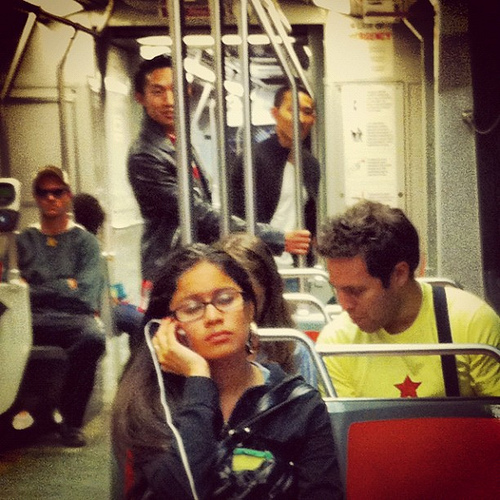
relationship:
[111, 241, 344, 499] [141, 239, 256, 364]
woman has a head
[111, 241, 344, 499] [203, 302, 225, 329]
woman has a nose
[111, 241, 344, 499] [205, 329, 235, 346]
woman has a mouth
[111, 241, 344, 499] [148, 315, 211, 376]
woman has a hand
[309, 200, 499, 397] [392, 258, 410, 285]
man has an ear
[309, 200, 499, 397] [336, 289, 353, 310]
man has a nose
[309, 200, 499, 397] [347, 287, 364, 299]
man has an eye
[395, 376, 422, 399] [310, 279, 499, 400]
star design on shirt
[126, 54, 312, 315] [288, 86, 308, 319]
man holding pole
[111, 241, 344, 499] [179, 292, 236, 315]
woman with closed eyes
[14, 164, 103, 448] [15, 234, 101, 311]
man crossed arms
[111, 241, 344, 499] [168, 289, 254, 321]
woman wearing glasses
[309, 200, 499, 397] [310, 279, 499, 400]
man in a shirt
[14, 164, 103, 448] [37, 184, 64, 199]
man wearing sunglasses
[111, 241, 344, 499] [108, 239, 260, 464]
woman has long hair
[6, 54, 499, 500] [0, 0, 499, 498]
people in a train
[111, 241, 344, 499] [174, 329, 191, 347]
woman holding device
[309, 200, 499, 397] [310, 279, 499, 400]
man in a yellow shirt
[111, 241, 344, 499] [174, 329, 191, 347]
woman on a cell phone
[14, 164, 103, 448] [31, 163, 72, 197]
man in a hat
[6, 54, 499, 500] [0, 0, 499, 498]
people on a train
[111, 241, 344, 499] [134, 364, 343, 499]
woman in a jacket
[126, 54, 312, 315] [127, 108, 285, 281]
man wearing a jacket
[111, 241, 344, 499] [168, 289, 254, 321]
woman with glasses